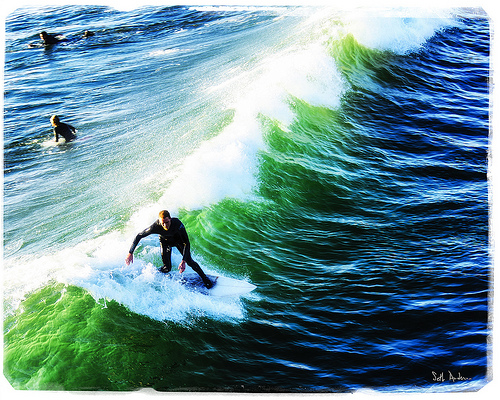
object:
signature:
[429, 368, 474, 384]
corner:
[394, 341, 498, 400]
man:
[125, 210, 214, 290]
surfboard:
[193, 273, 220, 296]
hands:
[124, 255, 186, 274]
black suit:
[129, 217, 190, 263]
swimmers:
[30, 26, 98, 51]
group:
[27, 29, 115, 53]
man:
[28, 31, 66, 50]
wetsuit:
[54, 122, 76, 139]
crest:
[294, 4, 403, 78]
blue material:
[203, 277, 214, 289]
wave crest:
[249, 11, 482, 209]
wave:
[299, 99, 484, 353]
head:
[158, 210, 171, 230]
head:
[40, 31, 49, 40]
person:
[51, 112, 80, 147]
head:
[50, 115, 60, 127]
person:
[78, 29, 112, 40]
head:
[84, 30, 87, 34]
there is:
[196, 198, 218, 213]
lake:
[0, 0, 490, 392]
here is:
[136, 23, 247, 60]